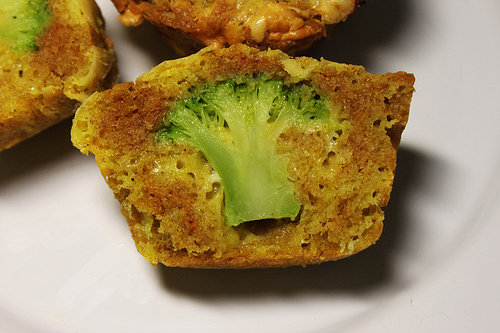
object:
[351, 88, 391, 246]
muffin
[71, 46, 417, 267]
brea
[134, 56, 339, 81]
muffin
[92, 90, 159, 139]
bread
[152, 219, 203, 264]
holes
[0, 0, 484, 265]
group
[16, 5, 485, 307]
plate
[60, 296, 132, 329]
wood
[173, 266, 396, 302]
shadow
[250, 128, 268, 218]
inside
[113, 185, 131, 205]
hole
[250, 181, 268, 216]
white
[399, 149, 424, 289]
black shadow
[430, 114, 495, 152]
white table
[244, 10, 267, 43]
crust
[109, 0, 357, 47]
cupcake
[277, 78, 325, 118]
green top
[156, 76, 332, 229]
broccoli